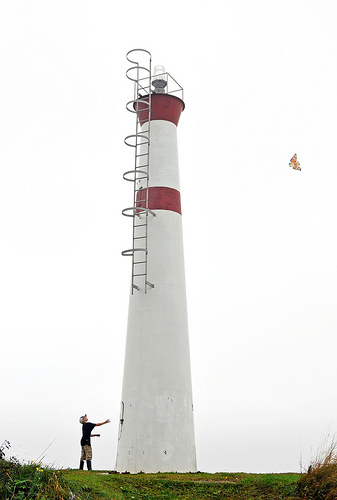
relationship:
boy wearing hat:
[79, 412, 110, 470] [79, 412, 86, 424]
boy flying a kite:
[79, 412, 110, 470] [266, 124, 318, 185]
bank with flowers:
[1, 463, 336, 498] [33, 463, 242, 499]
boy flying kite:
[80, 415, 110, 470] [290, 152, 302, 169]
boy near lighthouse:
[80, 415, 110, 470] [115, 93, 197, 473]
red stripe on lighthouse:
[131, 182, 184, 219] [115, 43, 198, 477]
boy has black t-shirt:
[79, 412, 110, 470] [80, 422, 96, 446]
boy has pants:
[79, 412, 110, 470] [79, 444, 92, 460]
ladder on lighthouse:
[120, 45, 153, 296] [115, 43, 198, 477]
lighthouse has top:
[115, 43, 198, 477] [132, 92, 185, 126]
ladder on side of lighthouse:
[121, 45, 156, 296] [115, 93, 197, 473]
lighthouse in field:
[94, 61, 214, 429] [25, 430, 220, 497]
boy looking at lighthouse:
[79, 412, 110, 470] [115, 93, 197, 473]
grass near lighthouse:
[18, 471, 308, 496] [118, 66, 191, 470]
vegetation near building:
[0, 440, 80, 498] [152, 152, 186, 208]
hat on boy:
[78, 413, 86, 423] [78, 413, 111, 470]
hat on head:
[78, 413, 86, 423] [78, 413, 87, 423]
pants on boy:
[73, 444, 94, 462] [56, 398, 124, 474]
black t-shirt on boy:
[78, 421, 95, 441] [69, 411, 115, 472]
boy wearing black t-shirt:
[79, 412, 110, 470] [80, 422, 96, 446]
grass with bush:
[46, 469, 301, 495] [294, 447, 334, 498]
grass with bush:
[46, 469, 301, 495] [0, 442, 66, 498]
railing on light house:
[117, 44, 161, 299] [106, 39, 211, 479]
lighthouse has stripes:
[115, 43, 198, 477] [128, 93, 185, 216]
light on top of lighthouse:
[149, 77, 168, 93] [115, 43, 198, 477]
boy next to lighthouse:
[79, 412, 110, 470] [115, 43, 198, 477]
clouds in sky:
[22, 20, 334, 475] [269, 37, 335, 94]